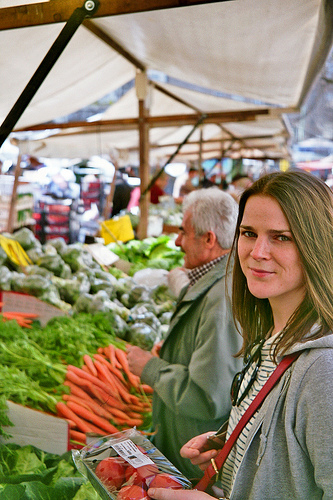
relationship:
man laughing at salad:
[139, 186, 247, 492] [0, 313, 161, 439]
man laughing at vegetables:
[130, 204, 267, 451] [10, 309, 150, 488]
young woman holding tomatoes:
[215, 168, 326, 475] [87, 412, 208, 495]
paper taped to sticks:
[101, 214, 140, 248] [105, 224, 128, 264]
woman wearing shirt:
[148, 171, 331, 500] [213, 346, 299, 479]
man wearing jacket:
[153, 186, 248, 447] [139, 256, 247, 480]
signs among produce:
[4, 202, 135, 253] [12, 227, 153, 322]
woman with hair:
[145, 170, 331, 499] [220, 162, 332, 368]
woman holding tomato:
[145, 170, 331, 499] [94, 455, 127, 489]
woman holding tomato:
[145, 170, 331, 499] [126, 460, 154, 486]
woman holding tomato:
[145, 170, 331, 499] [134, 441, 147, 453]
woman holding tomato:
[145, 170, 331, 499] [146, 468, 181, 489]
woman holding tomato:
[145, 170, 331, 499] [118, 485, 147, 499]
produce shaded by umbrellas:
[1, 219, 155, 344] [1, 2, 330, 163]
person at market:
[126, 187, 244, 475] [0, 86, 204, 498]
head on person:
[129, 140, 248, 288] [148, 198, 267, 409]